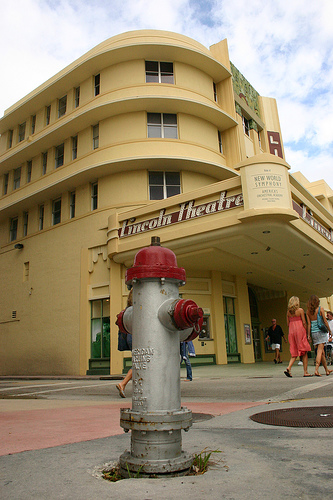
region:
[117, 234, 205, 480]
red and gray hydrant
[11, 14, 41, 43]
white clouds in blue sky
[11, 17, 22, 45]
white clouds in blue sky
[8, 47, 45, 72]
white clouds in blue sky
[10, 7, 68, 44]
white clouds in blue sky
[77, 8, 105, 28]
white clouds in blue sky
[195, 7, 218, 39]
white clouds in blue sky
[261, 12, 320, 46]
white clouds in blue sky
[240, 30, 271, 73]
white clouds in blue sky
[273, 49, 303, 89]
white clouds in blue sky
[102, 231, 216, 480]
red and silver fire hydrant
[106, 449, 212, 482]
grass growing beneath hydrant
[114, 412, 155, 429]
rusty edge on hydrant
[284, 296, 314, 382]
blonde woman in pink dress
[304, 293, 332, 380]
woman in denim skirt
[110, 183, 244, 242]
Lincoln theater unlit sign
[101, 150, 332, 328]
front awning on theater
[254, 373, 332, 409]
white crosswalk safety line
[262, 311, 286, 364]
man in white shorts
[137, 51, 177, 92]
fourth floor front window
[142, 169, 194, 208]
This is a window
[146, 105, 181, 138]
This is a window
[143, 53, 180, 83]
This is a window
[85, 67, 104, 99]
This is a window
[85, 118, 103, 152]
This is a window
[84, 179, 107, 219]
This is a window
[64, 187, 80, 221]
This is a window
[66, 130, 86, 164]
This is a window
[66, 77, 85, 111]
This is a window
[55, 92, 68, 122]
This is a window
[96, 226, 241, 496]
this is a fire hydrant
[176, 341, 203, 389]
this is a person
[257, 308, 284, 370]
this is a person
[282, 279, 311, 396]
this is a person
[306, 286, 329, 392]
this is a person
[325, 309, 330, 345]
this is a person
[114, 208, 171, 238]
a word on the building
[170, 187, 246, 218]
a word on the building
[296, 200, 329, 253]
a word on the building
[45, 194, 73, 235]
a window on the building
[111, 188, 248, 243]
words on the theater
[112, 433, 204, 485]
base of the hydrant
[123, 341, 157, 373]
word on the hydrant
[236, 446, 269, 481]
gray ground next to the hydrant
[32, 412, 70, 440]
red ground next to hydrant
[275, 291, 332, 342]
two women in the background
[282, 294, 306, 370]
lady wearing a light dress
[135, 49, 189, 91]
top window on building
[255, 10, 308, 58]
clouds in the sky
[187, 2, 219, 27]
blue sky above clouds